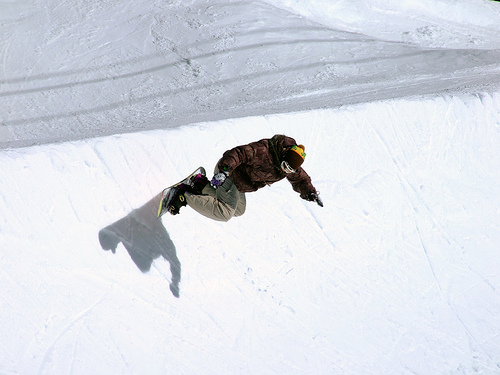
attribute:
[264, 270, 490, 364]
snow — blinding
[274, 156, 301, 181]
goggles — white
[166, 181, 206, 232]
sneakers — black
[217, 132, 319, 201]
coat — brown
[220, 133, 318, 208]
jacket — brown, thick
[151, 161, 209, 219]
board — multi-colored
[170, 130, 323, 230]
fellow — snowboarding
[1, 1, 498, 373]
ground — white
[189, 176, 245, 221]
pants — brown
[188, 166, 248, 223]
legs — bent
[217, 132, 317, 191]
jacket — brown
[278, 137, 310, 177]
hat — multi-colored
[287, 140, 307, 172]
cap — knitted 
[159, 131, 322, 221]
man — snowboarding 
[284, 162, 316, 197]
arm — outstretched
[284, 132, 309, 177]
cap — multicolored, knit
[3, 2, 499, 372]
snow — white